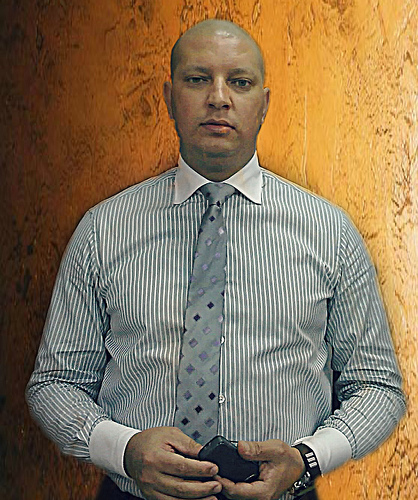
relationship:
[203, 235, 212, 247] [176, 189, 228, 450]
purple diamond on tie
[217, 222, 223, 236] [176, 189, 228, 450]
purple diamond on tie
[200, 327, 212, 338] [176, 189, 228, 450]
diamond on tie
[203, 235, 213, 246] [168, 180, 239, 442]
purple diamond on mans tie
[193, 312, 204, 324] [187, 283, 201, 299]
diamond on tie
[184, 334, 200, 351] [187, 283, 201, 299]
diamond on tie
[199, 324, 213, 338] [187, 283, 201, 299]
diamond on tie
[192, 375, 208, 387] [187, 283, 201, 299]
diamond on tie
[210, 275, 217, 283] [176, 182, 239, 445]
diamonds on tie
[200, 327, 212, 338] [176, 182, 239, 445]
diamond on tie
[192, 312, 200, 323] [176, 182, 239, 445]
diamond on tie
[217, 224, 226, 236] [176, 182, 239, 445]
purple diamond on tie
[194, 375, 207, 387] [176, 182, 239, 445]
diamond on tie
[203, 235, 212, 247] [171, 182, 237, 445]
purple diamond on tie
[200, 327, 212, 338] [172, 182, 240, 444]
diamond on man's tie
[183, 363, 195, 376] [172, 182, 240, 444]
diamond on man's tie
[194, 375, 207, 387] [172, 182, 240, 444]
diamond on man's tie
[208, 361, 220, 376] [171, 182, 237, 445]
diamond on tie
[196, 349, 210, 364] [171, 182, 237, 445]
diamond on tie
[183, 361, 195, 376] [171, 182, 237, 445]
diamond on tie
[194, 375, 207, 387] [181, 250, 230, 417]
diamond on tie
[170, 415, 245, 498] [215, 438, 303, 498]
phone in man's hand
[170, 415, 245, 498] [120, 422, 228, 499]
phone in hand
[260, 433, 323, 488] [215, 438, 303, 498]
watch on man's hand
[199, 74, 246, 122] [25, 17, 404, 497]
nose of man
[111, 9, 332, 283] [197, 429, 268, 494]
man holding cellphone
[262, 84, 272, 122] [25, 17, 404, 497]
left ear of man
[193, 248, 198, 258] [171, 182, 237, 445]
diamond on tie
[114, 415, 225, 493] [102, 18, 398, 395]
hand connected to man